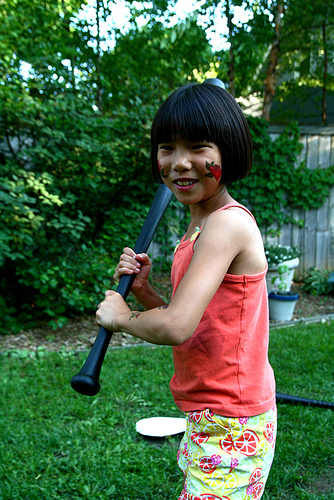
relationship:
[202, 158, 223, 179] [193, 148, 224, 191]
flower on cheek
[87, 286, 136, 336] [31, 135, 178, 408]
hand holds bat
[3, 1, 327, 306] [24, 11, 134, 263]
leaves on tree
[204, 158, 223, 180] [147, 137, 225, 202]
flower tattoo on face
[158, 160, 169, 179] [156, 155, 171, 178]
flower tattoo on cheek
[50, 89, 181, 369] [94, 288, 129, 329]
bat in hand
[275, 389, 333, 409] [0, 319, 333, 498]
baseball bat on ground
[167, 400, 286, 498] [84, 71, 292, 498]
shorts on girl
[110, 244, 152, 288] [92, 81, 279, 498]
hand on girl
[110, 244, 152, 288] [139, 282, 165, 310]
hand on arm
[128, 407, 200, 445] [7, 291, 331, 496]
racket on ground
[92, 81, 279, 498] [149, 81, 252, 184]
girl has hair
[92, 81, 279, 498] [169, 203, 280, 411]
girl wearing top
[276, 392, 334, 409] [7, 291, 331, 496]
baseball bat on ground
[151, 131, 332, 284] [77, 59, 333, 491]
fence behind girl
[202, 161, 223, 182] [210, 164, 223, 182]
drawing of a flower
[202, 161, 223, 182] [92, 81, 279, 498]
drawing on girl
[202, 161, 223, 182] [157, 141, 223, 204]
drawing on face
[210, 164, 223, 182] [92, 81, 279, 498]
flower on girl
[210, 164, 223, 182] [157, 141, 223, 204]
flower on face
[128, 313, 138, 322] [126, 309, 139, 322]
drawing of a rose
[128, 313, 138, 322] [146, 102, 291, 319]
drawing on girl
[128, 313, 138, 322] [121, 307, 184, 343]
drawing on arm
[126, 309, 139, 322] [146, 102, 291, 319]
rose on girl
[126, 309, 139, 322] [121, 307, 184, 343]
rose on arm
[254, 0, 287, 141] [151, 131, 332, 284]
tree behind fence